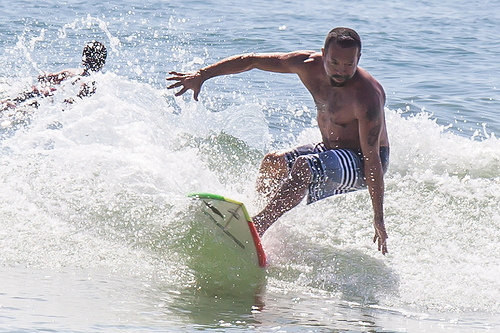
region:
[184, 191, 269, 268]
surfboard coming out of wave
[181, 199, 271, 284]
bottom of the surfboard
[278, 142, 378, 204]
board shorts of surfer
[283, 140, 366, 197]
black and white stripes on board shorts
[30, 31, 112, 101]
surfer behind wave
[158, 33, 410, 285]
surfer riding a wave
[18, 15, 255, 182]
splash surfer is kicking up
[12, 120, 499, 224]
white foam of wave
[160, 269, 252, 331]
reflection of surfboard on water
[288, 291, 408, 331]
reflection of surfer on water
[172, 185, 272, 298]
White surfboard in the water.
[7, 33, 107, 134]
Person in the water.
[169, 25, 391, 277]
Man surfing in the water.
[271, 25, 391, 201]
Man wearing gray shorts.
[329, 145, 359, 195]
Black and white stripes on gray shorts.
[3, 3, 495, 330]
Water in the forefront and background.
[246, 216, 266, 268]
Red rim on surfboard.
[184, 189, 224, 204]
Green rim on surfboard.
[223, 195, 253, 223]
Yellow trim on the surfboard.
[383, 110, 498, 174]
White splashes of water.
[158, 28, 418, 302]
the man is surfing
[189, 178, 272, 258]
a surfboard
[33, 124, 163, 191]
a splash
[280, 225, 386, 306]
a shadow on the water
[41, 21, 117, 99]
a person in the water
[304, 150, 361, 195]
shorts on man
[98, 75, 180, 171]
the water is white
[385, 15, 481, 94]
the water is blue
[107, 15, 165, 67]
a splash of water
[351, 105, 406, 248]
the mans arm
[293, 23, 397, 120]
The man has hair.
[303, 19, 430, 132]
The man's hair is short.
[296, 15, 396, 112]
The man's hair is dark.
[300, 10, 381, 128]
The man has a moustache.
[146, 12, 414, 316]
The man is on a surfboard.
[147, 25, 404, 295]
The surfboard is in the water.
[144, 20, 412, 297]
The man is wearing shorts.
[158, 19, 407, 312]
The man's shorts are striped.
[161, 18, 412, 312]
The man's shorts are blue and white.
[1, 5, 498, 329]
The water is splashing.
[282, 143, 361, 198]
Grey white and blue shorts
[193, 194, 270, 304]
surfboard in the water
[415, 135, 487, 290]
white cap of splashing waves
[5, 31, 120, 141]
Second surfer in the water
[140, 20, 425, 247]
Surfer with arms out for balance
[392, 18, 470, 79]
Calm blue sea behind surfer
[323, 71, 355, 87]
Gotee on man's face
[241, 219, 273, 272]
red corner of surfboard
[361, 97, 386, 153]
Tattoos on man's arm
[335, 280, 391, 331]
Reflection of man in water